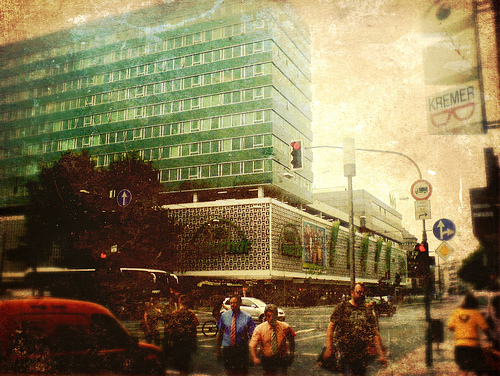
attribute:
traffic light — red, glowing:
[290, 139, 303, 171]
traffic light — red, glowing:
[415, 242, 429, 276]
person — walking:
[213, 294, 255, 375]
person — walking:
[250, 301, 297, 374]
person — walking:
[164, 291, 200, 374]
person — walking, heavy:
[321, 281, 389, 374]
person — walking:
[140, 297, 164, 344]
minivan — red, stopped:
[0, 294, 165, 374]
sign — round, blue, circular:
[431, 217, 457, 242]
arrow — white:
[446, 226, 454, 236]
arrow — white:
[436, 217, 446, 230]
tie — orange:
[229, 312, 237, 347]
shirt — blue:
[217, 308, 256, 346]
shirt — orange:
[250, 320, 297, 357]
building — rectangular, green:
[3, 2, 313, 305]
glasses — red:
[430, 101, 474, 128]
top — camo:
[330, 299, 380, 362]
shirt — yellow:
[448, 307, 489, 345]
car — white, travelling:
[220, 293, 285, 329]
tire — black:
[201, 319, 220, 338]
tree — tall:
[16, 145, 183, 307]